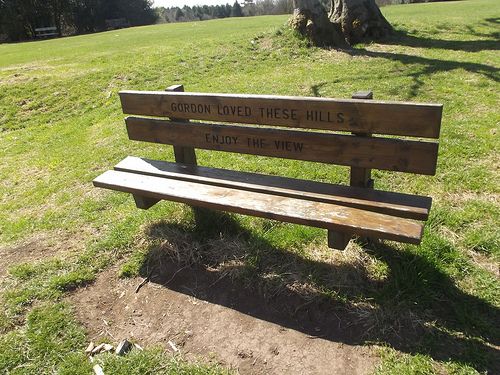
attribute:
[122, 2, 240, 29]
trees — near bench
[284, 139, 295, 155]
letter 'e' — on bench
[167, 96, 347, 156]
writing — black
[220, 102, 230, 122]
letter — black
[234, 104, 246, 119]
letter 'e' — black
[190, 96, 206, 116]
letter "o" — black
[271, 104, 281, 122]
"e" — on bench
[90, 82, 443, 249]
bench — wood, on bench, near bench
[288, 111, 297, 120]
e — black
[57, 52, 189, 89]
grass — green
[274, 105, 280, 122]
e — black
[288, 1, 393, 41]
tree — near bench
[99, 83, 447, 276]
bench — near bench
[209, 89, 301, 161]
letter — black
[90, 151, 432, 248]
seat — brown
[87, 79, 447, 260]
tebench — on bench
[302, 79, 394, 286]
support — metal